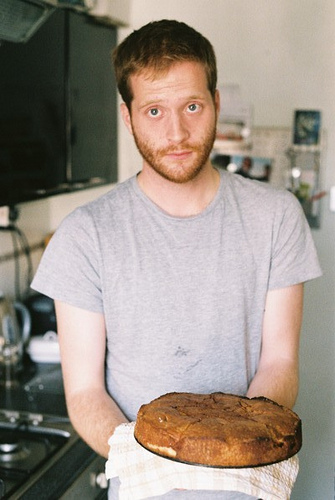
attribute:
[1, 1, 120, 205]
cabinet — black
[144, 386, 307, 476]
cake — delicious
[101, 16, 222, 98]
hair — brown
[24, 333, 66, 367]
butter container — white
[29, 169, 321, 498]
t-shirt — gray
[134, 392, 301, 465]
cake — freshly baked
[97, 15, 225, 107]
hair — brown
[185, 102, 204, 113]
eye — blue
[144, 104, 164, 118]
eye — blue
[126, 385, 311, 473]
cake — cooked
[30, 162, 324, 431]
t shirt — gray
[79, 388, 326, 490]
towel — white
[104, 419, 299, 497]
cloth — white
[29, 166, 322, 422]
shirt — grey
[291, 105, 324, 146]
picture — blurry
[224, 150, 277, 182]
picture — blurry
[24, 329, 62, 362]
container — white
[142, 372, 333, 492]
bread — brown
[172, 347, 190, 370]
stain — small